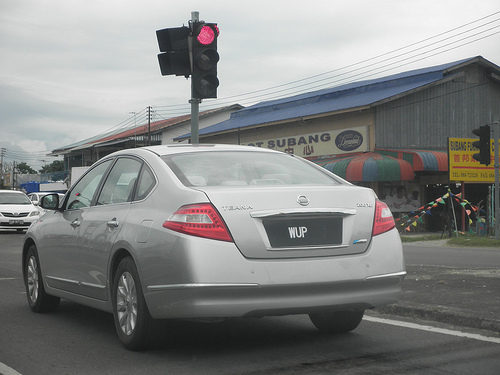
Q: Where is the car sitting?
A: Stop light.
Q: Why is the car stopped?
A: Red light.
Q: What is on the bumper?
A: License plate.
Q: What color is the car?
A: Silver.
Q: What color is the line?
A: White.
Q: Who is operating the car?
A: Driver.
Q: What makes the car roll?
A: Tires.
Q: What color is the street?
A: Black.